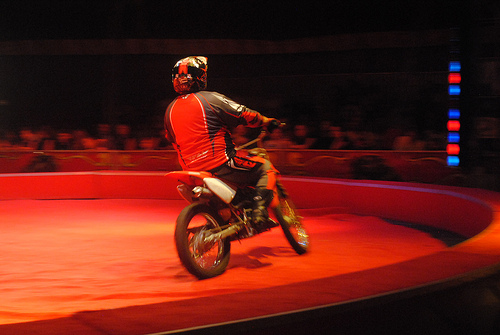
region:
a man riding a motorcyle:
[143, 39, 315, 282]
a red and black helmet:
[163, 52, 212, 96]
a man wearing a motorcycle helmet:
[149, 47, 294, 173]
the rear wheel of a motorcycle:
[171, 203, 237, 280]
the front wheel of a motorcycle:
[268, 184, 312, 253]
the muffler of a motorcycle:
[173, 175, 207, 205]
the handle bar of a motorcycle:
[238, 123, 271, 143]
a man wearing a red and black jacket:
[146, 55, 283, 184]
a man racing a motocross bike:
[124, 50, 326, 275]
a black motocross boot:
[243, 183, 282, 231]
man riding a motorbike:
[140, 45, 368, 313]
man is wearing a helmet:
[158, 49, 237, 139]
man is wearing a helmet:
[136, 30, 223, 110]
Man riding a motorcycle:
[137, 34, 427, 305]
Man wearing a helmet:
[155, 38, 241, 101]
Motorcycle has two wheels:
[146, 153, 396, 293]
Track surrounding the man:
[58, 165, 355, 330]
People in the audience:
[312, 105, 489, 158]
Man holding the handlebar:
[241, 93, 287, 155]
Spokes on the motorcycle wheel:
[189, 213, 235, 290]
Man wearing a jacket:
[160, 81, 292, 189]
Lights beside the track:
[445, 59, 479, 181]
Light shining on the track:
[42, 170, 119, 317]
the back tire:
[170, 233, 188, 248]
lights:
[438, 59, 466, 169]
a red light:
[446, 73, 460, 83]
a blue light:
[447, 132, 458, 141]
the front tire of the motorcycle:
[277, 228, 301, 244]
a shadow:
[232, 247, 261, 267]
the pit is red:
[21, 211, 123, 258]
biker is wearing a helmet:
[172, 59, 208, 93]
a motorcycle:
[148, 199, 309, 275]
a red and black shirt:
[160, 93, 235, 170]